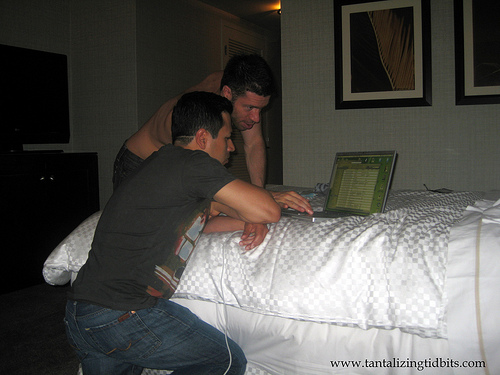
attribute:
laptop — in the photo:
[302, 149, 399, 219]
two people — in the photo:
[56, 51, 323, 371]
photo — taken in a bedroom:
[4, 2, 478, 367]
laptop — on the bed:
[279, 145, 400, 221]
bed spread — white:
[238, 196, 445, 371]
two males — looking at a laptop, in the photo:
[62, 47, 318, 373]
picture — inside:
[5, 5, 498, 374]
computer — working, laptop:
[298, 147, 402, 223]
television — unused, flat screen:
[2, 44, 81, 150]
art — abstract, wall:
[327, 0, 441, 116]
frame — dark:
[326, 6, 434, 114]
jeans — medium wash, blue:
[54, 285, 236, 374]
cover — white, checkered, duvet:
[177, 213, 466, 343]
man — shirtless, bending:
[119, 45, 284, 229]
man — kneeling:
[60, 90, 306, 372]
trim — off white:
[464, 217, 499, 372]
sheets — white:
[43, 193, 499, 372]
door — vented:
[244, 15, 287, 204]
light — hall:
[255, 1, 287, 18]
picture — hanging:
[451, 6, 499, 107]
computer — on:
[296, 138, 404, 230]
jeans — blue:
[66, 292, 246, 372]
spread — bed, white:
[35, 185, 496, 372]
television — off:
[0, 41, 94, 158]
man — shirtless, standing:
[110, 45, 289, 219]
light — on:
[268, 5, 288, 26]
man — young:
[203, 59, 292, 160]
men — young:
[143, 35, 310, 236]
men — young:
[128, 46, 295, 202]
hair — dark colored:
[234, 55, 283, 104]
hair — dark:
[236, 62, 296, 114]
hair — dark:
[172, 77, 217, 127]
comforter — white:
[285, 208, 419, 335]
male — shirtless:
[203, 59, 283, 153]